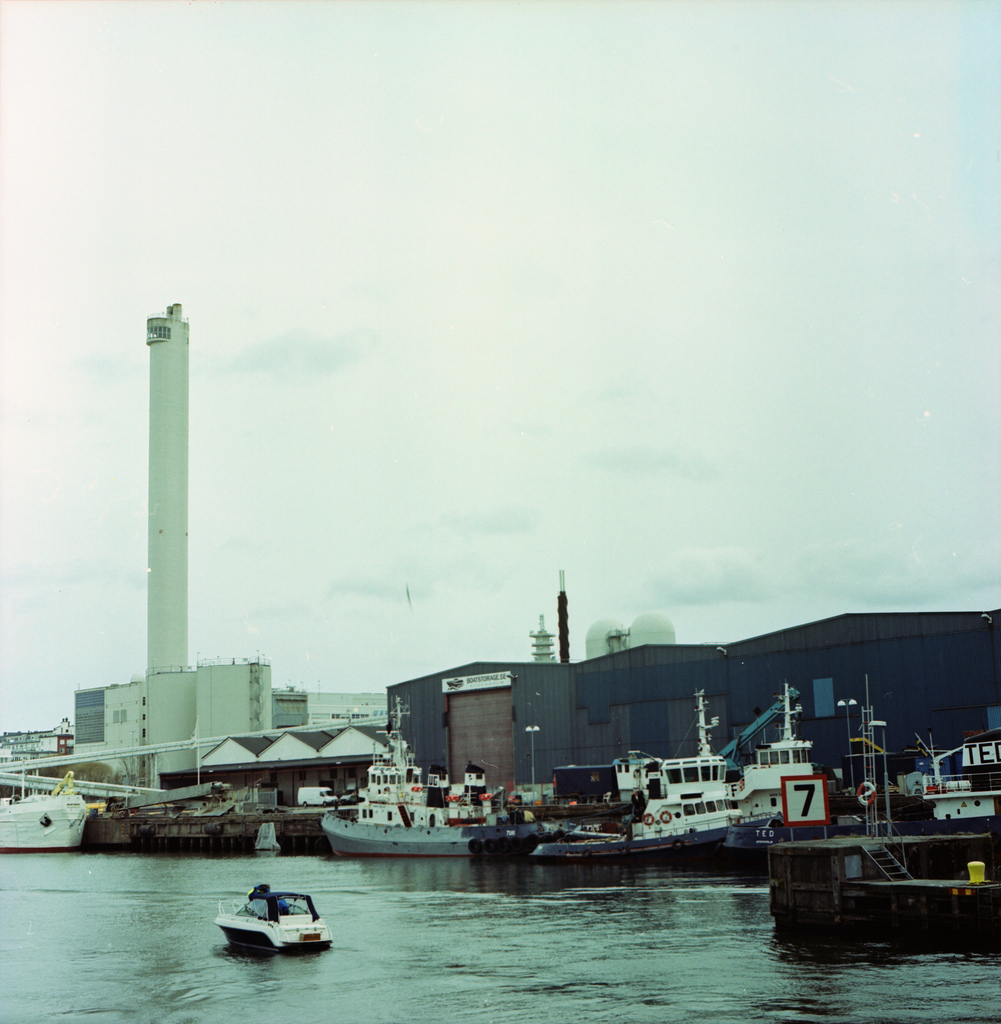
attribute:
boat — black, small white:
[208, 864, 369, 971]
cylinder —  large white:
[144, 300, 213, 664]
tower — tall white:
[124, 291, 244, 749]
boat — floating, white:
[179, 880, 351, 985]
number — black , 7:
[777, 777, 827, 846]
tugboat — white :
[206, 877, 344, 962]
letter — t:
[461, 671, 506, 681]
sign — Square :
[765, 773, 861, 825]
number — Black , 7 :
[788, 788, 820, 820]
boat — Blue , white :
[211, 857, 340, 955]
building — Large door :
[382, 653, 806, 896]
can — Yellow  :
[965, 857, 968, 891]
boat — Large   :
[310, 768, 528, 891]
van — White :
[4, 764, 124, 864]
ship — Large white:
[301, 758, 821, 963]